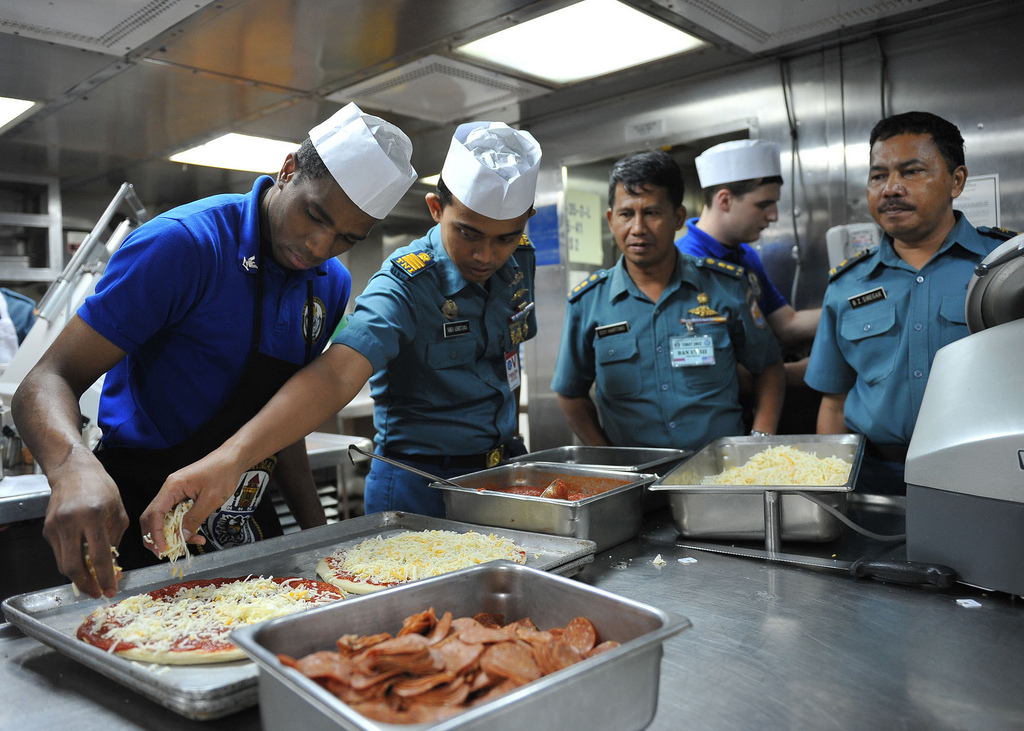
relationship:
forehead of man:
[311, 181, 372, 242] [11, 101, 415, 598]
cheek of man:
[264, 203, 303, 245] [11, 101, 415, 598]